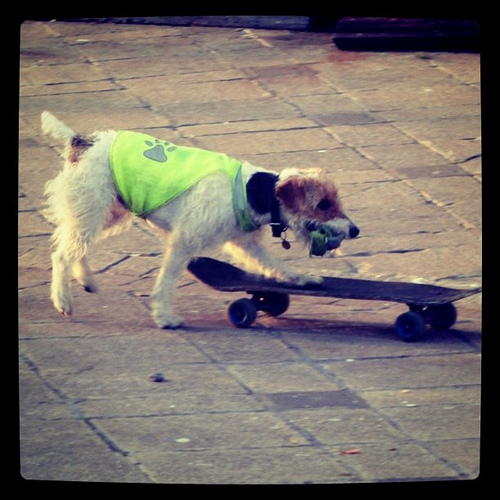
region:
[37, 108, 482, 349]
a dog riding on a skateboard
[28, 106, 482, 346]
a dog with it's left front pawn on a skateboard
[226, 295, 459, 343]
the wheels of a skateboard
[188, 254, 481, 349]
a black skateboard with black wheels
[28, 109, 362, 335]
a white dog with brown area on the face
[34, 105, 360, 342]
a dog with a yellowish colored shirt on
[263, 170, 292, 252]
the collar that is on a dog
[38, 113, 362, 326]
a dog with an object in it's mouth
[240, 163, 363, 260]
the dog has a big black spot on it's neck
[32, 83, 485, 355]
the dog has one paw on the skateboard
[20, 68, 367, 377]
the dog is wearing a vest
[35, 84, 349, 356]
the vest is neon green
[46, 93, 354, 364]
the vest is reflective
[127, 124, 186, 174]
there is a paw print on the vest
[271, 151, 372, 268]
the dog has a toy in his mouth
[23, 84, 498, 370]
a dog is riding a skateboard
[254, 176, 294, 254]
the dog has a black collar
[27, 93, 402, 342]
the dog is white and brown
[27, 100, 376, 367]
the dog has shaggy fur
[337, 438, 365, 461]
a leaf on the ground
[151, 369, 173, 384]
a rock on the ground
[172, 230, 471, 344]
a skateboard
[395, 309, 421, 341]
the wheel on the skateboard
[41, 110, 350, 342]
a dog wearing a green shirt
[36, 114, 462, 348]
a dog stepping on a skateboard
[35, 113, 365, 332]
a white and brown dog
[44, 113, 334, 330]
a dog with a toy in its mouth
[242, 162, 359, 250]
a dog with a collar on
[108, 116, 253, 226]
yellow vest on the dog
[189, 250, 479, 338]
black skateboard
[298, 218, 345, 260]
dog has something in it's mouth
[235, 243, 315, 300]
dog has it's paw on the skateboard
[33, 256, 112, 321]
dog's back paws are in the air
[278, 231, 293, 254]
tag on the dog's collar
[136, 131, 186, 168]
paw print on the dog's vest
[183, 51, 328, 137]
brick pavement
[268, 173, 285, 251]
dog is wearing a collar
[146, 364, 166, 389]
rock on the pavement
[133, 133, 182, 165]
paw print on the vest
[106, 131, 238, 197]
yellow vest on the dog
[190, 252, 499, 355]
skateboard on the ground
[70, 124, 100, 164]
brown spot on the back of the dog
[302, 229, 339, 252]
something in dog's mouth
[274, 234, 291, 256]
tag on the collar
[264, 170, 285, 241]
black dog collar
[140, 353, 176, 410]
rock on the ground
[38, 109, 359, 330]
small white furry dog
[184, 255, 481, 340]
small long black skateboard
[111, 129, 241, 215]
small green cloth vest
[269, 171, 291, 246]
long black metal collar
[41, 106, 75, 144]
short white furry dog tail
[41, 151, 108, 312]
short fluffy white leg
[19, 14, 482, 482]
large open stone area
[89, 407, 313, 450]
square small stone brick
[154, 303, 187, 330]
small white furry paw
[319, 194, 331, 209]
small round black eye